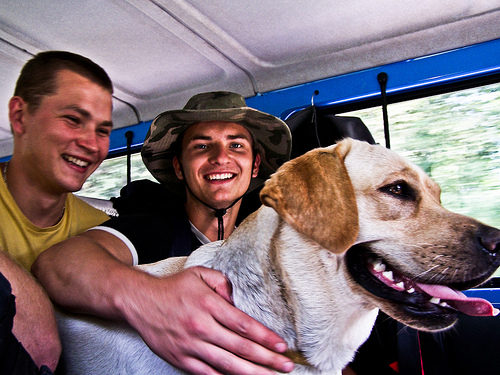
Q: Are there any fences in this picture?
A: No, there are no fences.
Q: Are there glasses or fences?
A: No, there are no fences or glasses.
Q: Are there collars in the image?
A: Yes, there is a collar.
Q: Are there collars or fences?
A: Yes, there is a collar.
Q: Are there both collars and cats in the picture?
A: No, there is a collar but no cats.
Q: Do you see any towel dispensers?
A: No, there are no towel dispensers.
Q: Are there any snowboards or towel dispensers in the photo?
A: No, there are no towel dispensers or snowboards.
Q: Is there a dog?
A: Yes, there is a dog.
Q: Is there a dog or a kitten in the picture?
A: Yes, there is a dog.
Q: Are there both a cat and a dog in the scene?
A: No, there is a dog but no cats.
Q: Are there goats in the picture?
A: No, there are no goats.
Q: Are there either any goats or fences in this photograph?
A: No, there are no goats or fences.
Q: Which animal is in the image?
A: The animal is a dog.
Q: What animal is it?
A: The animal is a dog.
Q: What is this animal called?
A: This is a dog.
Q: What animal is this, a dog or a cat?
A: This is a dog.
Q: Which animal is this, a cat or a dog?
A: This is a dog.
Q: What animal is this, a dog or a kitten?
A: This is a dog.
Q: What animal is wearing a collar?
A: The dog is wearing a collar.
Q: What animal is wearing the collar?
A: The dog is wearing a collar.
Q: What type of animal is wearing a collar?
A: The animal is a dog.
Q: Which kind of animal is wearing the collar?
A: The animal is a dog.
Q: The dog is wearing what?
A: The dog is wearing a collar.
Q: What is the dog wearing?
A: The dog is wearing a collar.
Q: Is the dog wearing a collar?
A: Yes, the dog is wearing a collar.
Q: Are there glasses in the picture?
A: No, there are no glasses.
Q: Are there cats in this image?
A: No, there are no cats.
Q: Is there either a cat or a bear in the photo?
A: No, there are no cats or bears.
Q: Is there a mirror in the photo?
A: No, there are no mirrors.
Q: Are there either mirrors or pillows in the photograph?
A: No, there are no mirrors or pillows.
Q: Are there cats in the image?
A: No, there are no cats.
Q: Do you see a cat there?
A: No, there are no cats.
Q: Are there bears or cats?
A: No, there are no cats or bears.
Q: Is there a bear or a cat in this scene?
A: No, there are no cats or bears.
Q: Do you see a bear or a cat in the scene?
A: No, there are no cats or bears.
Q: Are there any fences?
A: No, there are no fences.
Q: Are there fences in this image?
A: No, there are no fences.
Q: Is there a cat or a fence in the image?
A: No, there are no fences or cats.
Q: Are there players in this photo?
A: No, there are no players.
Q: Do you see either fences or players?
A: No, there are no players or fences.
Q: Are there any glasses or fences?
A: No, there are no fences or glasses.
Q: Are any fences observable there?
A: No, there are no fences.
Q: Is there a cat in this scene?
A: No, there are no cats.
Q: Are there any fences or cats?
A: No, there are no cats or fences.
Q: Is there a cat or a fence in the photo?
A: No, there are no cats or fences.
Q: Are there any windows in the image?
A: Yes, there is a window.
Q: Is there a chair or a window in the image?
A: Yes, there is a window.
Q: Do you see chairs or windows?
A: Yes, there is a window.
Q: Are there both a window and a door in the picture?
A: No, there is a window but no doors.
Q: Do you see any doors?
A: No, there are no doors.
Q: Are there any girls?
A: No, there are no girls.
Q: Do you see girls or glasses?
A: No, there are no girls or glasses.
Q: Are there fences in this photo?
A: No, there are no fences.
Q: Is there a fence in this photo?
A: No, there are no fences.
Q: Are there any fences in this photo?
A: No, there are no fences.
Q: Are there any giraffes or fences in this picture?
A: No, there are no fences or giraffes.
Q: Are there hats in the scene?
A: Yes, there is a hat.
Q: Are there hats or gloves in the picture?
A: Yes, there is a hat.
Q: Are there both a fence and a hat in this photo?
A: No, there is a hat but no fences.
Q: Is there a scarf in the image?
A: No, there are no scarves.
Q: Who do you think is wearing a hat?
A: The man is wearing a hat.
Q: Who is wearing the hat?
A: The man is wearing a hat.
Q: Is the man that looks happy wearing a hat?
A: Yes, the man is wearing a hat.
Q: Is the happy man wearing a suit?
A: No, the man is wearing a hat.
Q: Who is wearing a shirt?
A: The man is wearing a shirt.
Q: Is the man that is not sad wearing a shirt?
A: Yes, the man is wearing a shirt.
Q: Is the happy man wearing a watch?
A: No, the man is wearing a shirt.